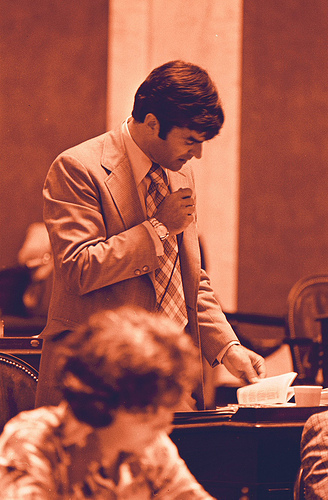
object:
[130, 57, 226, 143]
hair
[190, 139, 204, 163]
nose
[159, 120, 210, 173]
face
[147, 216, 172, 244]
watch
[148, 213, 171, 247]
wrist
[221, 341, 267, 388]
hand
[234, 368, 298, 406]
page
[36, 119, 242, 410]
suit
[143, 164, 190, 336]
tie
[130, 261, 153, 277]
two buttons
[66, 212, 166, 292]
sleeve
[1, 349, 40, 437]
chair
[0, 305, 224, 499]
person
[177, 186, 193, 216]
microphone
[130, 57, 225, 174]
head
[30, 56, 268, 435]
man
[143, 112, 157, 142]
ear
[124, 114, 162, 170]
neck